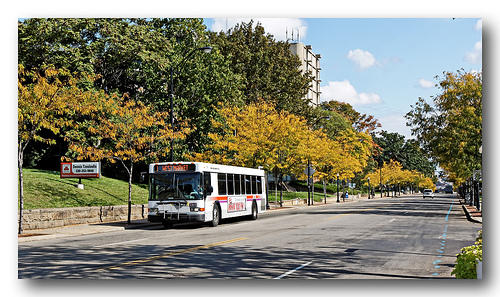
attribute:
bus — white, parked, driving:
[141, 166, 265, 223]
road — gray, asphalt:
[32, 194, 463, 292]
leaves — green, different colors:
[154, 85, 170, 94]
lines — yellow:
[130, 238, 248, 273]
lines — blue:
[432, 206, 458, 270]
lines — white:
[281, 248, 328, 271]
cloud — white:
[347, 44, 373, 71]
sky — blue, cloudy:
[286, 21, 499, 152]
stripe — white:
[268, 247, 307, 282]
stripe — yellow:
[124, 228, 238, 273]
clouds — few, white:
[325, 50, 385, 104]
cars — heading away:
[423, 190, 459, 210]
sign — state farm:
[62, 156, 103, 177]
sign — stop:
[305, 164, 317, 175]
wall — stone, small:
[28, 203, 133, 223]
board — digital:
[151, 166, 199, 173]